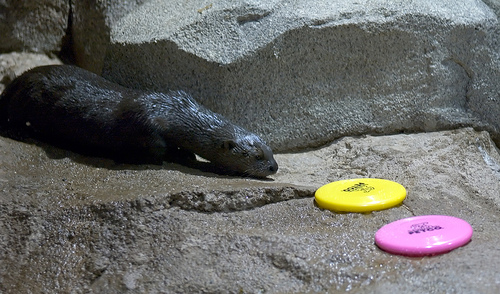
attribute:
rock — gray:
[2, 1, 496, 158]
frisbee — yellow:
[333, 173, 385, 213]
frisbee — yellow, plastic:
[297, 165, 413, 206]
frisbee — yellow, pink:
[320, 178, 407, 215]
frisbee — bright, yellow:
[277, 169, 477, 268]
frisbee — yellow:
[310, 172, 412, 215]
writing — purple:
[406, 217, 445, 239]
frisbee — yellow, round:
[313, 176, 408, 213]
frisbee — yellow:
[320, 170, 418, 215]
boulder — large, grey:
[1, 2, 496, 289]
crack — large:
[452, 53, 478, 118]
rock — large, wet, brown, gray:
[0, 53, 500, 290]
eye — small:
[237, 151, 275, 166]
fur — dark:
[60, 77, 110, 125]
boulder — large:
[93, 6, 488, 131]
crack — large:
[127, 180, 321, 220]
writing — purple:
[404, 220, 441, 235]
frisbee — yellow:
[342, 172, 377, 199]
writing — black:
[336, 168, 386, 200]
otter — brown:
[2, 65, 277, 179]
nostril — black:
[267, 163, 274, 170]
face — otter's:
[245, 141, 278, 181]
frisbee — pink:
[377, 200, 477, 262]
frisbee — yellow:
[309, 172, 421, 224]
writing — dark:
[344, 180, 374, 197]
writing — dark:
[344, 179, 370, 194]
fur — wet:
[1, 92, 184, 160]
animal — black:
[0, 63, 279, 179]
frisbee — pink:
[375, 210, 475, 260]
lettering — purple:
[406, 218, 442, 236]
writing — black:
[339, 177, 375, 194]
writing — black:
[407, 219, 442, 235]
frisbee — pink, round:
[372, 213, 472, 259]